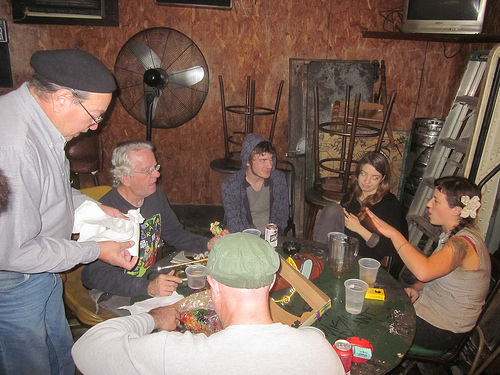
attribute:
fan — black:
[109, 24, 214, 140]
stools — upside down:
[199, 57, 424, 199]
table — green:
[131, 214, 380, 373]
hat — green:
[180, 237, 277, 292]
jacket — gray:
[215, 126, 298, 232]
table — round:
[135, 230, 420, 367]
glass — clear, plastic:
[340, 272, 366, 326]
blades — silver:
[131, 33, 203, 88]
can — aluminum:
[265, 221, 280, 248]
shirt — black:
[340, 183, 403, 252]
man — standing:
[3, 34, 145, 373]